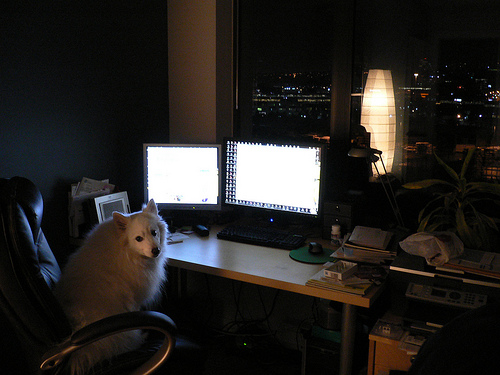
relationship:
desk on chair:
[55, 198, 168, 373] [1, 176, 205, 368]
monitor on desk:
[141, 142, 220, 212] [55, 188, 408, 374]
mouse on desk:
[307, 241, 325, 257] [55, 188, 408, 374]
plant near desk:
[406, 154, 499, 251] [55, 188, 408, 374]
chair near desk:
[1, 176, 205, 368] [55, 188, 408, 374]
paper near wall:
[71, 176, 115, 234] [1, 1, 165, 228]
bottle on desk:
[328, 222, 343, 246] [55, 188, 408, 374]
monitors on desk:
[143, 138, 328, 210] [55, 188, 408, 374]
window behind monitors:
[231, 2, 498, 217] [143, 138, 328, 210]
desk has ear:
[55, 198, 168, 373] [110, 213, 133, 235]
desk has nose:
[55, 198, 168, 373] [151, 245, 160, 257]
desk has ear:
[55, 198, 168, 373] [143, 198, 162, 215]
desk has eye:
[55, 198, 168, 373] [136, 235, 144, 244]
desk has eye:
[55, 198, 168, 373] [151, 228, 159, 239]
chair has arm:
[1, 176, 205, 368] [39, 310, 182, 375]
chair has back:
[1, 176, 205, 368] [3, 178, 61, 374]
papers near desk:
[66, 177, 119, 240] [55, 188, 408, 374]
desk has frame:
[55, 188, 408, 374] [24, 282, 391, 375]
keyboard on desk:
[216, 224, 306, 250] [55, 188, 408, 374]